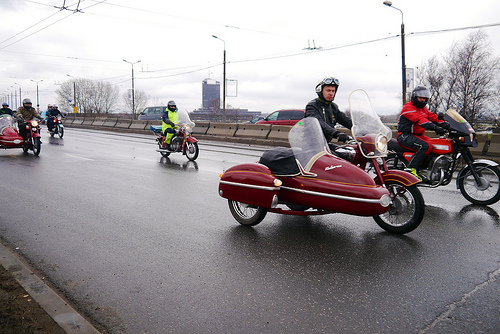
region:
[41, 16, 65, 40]
white clouds in blue sky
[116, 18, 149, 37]
white clouds in blue sky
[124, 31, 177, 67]
white clouds in blue sky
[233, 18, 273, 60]
white clouds in blue sky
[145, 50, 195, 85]
gray and white clouds in blue sky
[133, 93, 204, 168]
red bike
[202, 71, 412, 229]
red bike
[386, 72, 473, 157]
red bike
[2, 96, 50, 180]
red bike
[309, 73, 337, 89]
The helmet is white.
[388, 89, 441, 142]
His jacket is red.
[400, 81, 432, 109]
His helmet is black.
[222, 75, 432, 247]
His bike is maroon.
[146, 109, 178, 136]
His jacket is yellow.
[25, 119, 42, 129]
His light is on.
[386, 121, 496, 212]
His bike is red.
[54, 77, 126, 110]
The tree is bare.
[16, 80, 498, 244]
They are riding bikes.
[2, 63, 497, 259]
They are riding down the street.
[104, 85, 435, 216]
People riding motorcycles on the steet.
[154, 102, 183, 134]
The person is wearing a yellow raincoat.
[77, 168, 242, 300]
The road is wet.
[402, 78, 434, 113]
Person is wearing a helmet with a shield.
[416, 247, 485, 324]
A crack in the road.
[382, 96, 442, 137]
The jacket is red and black.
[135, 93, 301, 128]
Cars on the other side of highway.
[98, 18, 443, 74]
The sky is full of clouds.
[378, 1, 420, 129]
A street light on the pole.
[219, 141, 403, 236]
a small cart next to motorcycle.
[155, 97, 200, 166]
Man wearing red on a motorcycle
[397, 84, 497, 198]
Man wearing red on motorcycle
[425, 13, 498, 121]
Tree under a powerline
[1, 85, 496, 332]
Street full of people on motorcycles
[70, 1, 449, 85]
A line of street lights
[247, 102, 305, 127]
Red car on the other side of the highway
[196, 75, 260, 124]
Buidling in the back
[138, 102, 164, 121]
Blue car on the other side of the highway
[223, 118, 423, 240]
An empty partner bike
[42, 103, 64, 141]
Two people on one bike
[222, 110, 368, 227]
side cart of a motorcycle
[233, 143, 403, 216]
motorcycle is maroon red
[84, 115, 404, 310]
pavement is wet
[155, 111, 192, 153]
rider is wearing yellow jacket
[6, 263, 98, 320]
dirt on the side of the road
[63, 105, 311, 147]
concrete barrier center divider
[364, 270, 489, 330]
crack in the asphalt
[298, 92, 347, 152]
rider wearing a black jacket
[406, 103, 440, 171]
rider wearing a red outfit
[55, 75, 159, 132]
trees are missing leaves